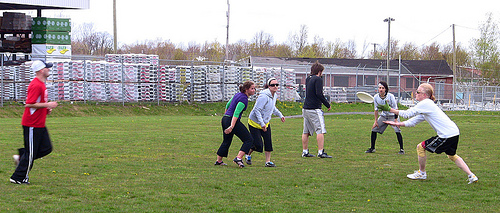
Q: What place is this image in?
A: It is at the field.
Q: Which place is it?
A: It is a field.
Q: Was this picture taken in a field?
A: Yes, it was taken in a field.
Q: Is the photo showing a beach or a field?
A: It is showing a field.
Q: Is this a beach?
A: No, it is a field.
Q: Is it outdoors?
A: Yes, it is outdoors.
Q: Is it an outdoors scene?
A: Yes, it is outdoors.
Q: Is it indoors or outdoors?
A: It is outdoors.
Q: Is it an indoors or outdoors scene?
A: It is outdoors.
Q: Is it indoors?
A: No, it is outdoors.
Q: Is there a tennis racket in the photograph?
A: No, there are no rackets.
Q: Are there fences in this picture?
A: Yes, there is a fence.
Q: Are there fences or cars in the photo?
A: Yes, there is a fence.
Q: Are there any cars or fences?
A: Yes, there is a fence.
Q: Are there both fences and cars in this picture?
A: No, there is a fence but no cars.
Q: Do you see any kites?
A: No, there are no kites.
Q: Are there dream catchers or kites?
A: No, there are no kites or dream catchers.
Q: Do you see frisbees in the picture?
A: Yes, there is a frisbee.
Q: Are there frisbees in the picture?
A: Yes, there is a frisbee.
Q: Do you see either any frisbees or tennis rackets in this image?
A: Yes, there is a frisbee.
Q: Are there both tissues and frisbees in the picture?
A: No, there is a frisbee but no tissues.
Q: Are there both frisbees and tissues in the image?
A: No, there is a frisbee but no tissues.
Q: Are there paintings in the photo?
A: No, there are no paintings.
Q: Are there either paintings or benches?
A: No, there are no paintings or benches.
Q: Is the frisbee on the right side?
A: Yes, the frisbee is on the right of the image.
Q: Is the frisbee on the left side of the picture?
A: No, the frisbee is on the right of the image.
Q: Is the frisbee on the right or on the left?
A: The frisbee is on the right of the image.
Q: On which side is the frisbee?
A: The frisbee is on the right of the image.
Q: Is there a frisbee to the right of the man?
A: Yes, there is a frisbee to the right of the man.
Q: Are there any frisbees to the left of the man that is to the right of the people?
A: No, the frisbee is to the right of the man.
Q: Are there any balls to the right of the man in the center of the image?
A: No, there is a frisbee to the right of the man.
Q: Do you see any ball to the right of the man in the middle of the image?
A: No, there is a frisbee to the right of the man.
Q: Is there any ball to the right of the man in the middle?
A: No, there is a frisbee to the right of the man.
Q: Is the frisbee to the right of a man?
A: Yes, the frisbee is to the right of a man.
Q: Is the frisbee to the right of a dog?
A: No, the frisbee is to the right of a man.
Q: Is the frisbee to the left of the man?
A: No, the frisbee is to the right of the man.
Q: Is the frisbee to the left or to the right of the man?
A: The frisbee is to the right of the man.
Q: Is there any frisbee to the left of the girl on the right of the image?
A: Yes, there is a frisbee to the left of the girl.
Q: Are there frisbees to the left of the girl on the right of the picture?
A: Yes, there is a frisbee to the left of the girl.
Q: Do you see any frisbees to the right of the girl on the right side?
A: No, the frisbee is to the left of the girl.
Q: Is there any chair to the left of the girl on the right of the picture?
A: No, there is a frisbee to the left of the girl.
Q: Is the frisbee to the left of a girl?
A: Yes, the frisbee is to the left of a girl.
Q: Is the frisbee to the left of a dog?
A: No, the frisbee is to the left of a girl.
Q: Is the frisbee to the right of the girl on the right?
A: No, the frisbee is to the left of the girl.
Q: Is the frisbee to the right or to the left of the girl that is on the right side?
A: The frisbee is to the left of the girl.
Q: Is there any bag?
A: No, there are no bags.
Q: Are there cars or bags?
A: No, there are no bags or cars.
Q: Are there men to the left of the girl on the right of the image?
A: Yes, there is a man to the left of the girl.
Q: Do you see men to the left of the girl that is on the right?
A: Yes, there is a man to the left of the girl.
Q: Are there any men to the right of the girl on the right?
A: No, the man is to the left of the girl.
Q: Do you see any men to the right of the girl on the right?
A: No, the man is to the left of the girl.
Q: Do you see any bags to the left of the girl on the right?
A: No, there is a man to the left of the girl.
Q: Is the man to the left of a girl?
A: Yes, the man is to the left of a girl.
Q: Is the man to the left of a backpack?
A: No, the man is to the left of a girl.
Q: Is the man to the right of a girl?
A: No, the man is to the left of a girl.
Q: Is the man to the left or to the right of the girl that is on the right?
A: The man is to the left of the girl.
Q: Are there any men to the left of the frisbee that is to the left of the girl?
A: Yes, there is a man to the left of the frisbee.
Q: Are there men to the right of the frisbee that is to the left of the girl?
A: No, the man is to the left of the frisbee.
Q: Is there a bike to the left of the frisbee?
A: No, there is a man to the left of the frisbee.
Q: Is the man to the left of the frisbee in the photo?
A: Yes, the man is to the left of the frisbee.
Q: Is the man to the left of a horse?
A: No, the man is to the left of the frisbee.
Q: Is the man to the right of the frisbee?
A: No, the man is to the left of the frisbee.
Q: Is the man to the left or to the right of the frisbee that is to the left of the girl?
A: The man is to the left of the frisbee.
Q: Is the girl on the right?
A: Yes, the girl is on the right of the image.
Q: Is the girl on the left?
A: No, the girl is on the right of the image.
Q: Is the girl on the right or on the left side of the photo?
A: The girl is on the right of the image.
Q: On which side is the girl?
A: The girl is on the right of the image.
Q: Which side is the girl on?
A: The girl is on the right of the image.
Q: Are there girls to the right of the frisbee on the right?
A: Yes, there is a girl to the right of the frisbee.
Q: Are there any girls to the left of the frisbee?
A: No, the girl is to the right of the frisbee.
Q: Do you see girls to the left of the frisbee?
A: No, the girl is to the right of the frisbee.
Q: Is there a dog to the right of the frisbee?
A: No, there is a girl to the right of the frisbee.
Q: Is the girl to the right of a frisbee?
A: Yes, the girl is to the right of a frisbee.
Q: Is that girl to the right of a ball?
A: No, the girl is to the right of a frisbee.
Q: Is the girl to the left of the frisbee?
A: No, the girl is to the right of the frisbee.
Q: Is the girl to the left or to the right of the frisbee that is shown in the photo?
A: The girl is to the right of the frisbee.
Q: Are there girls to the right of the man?
A: Yes, there is a girl to the right of the man.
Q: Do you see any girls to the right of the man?
A: Yes, there is a girl to the right of the man.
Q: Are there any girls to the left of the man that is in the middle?
A: No, the girl is to the right of the man.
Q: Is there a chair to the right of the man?
A: No, there is a girl to the right of the man.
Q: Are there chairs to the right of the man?
A: No, there is a girl to the right of the man.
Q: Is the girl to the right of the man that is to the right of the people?
A: Yes, the girl is to the right of the man.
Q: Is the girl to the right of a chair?
A: No, the girl is to the right of the man.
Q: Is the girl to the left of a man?
A: No, the girl is to the right of a man.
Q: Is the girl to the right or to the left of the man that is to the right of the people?
A: The girl is to the right of the man.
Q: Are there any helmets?
A: No, there are no helmets.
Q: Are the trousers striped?
A: Yes, the trousers are striped.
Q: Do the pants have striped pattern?
A: Yes, the pants are striped.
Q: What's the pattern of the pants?
A: The trousers are striped.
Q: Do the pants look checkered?
A: No, the pants are striped.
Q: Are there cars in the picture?
A: No, there are no cars.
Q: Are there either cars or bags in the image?
A: No, there are no cars or bags.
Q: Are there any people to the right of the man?
A: Yes, there are people to the right of the man.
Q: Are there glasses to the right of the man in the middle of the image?
A: No, there are people to the right of the man.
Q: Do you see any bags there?
A: No, there are no bags.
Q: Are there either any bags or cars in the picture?
A: No, there are no bags or cars.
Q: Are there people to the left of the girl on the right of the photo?
A: Yes, there are people to the left of the girl.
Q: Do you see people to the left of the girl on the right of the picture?
A: Yes, there are people to the left of the girl.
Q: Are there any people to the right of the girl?
A: No, the people are to the left of the girl.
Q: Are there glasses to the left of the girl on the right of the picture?
A: No, there are people to the left of the girl.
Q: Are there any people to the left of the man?
A: Yes, there are people to the left of the man.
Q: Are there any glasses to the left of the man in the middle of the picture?
A: No, there are people to the left of the man.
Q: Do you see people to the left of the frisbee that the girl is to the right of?
A: Yes, there are people to the left of the frisbee.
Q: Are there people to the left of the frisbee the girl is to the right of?
A: Yes, there are people to the left of the frisbee.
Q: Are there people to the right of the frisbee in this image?
A: No, the people are to the left of the frisbee.